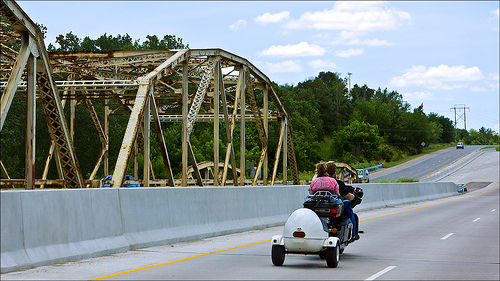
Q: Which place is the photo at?
A: It is at the road.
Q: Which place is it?
A: It is a road.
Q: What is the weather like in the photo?
A: It is cloudy.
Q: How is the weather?
A: It is cloudy.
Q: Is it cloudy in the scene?
A: Yes, it is cloudy.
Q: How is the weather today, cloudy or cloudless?
A: It is cloudy.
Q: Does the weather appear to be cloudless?
A: No, it is cloudy.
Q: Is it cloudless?
A: No, it is cloudy.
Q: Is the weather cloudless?
A: No, it is cloudy.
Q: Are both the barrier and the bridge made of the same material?
A: No, the barrier is made of cement and the bridge is made of metal.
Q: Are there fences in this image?
A: No, there are no fences.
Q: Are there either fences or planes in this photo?
A: No, there are no fences or planes.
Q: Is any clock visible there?
A: No, there are no clocks.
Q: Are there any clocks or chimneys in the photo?
A: No, there are no clocks or chimneys.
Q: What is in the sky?
A: The clouds are in the sky.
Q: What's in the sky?
A: The clouds are in the sky.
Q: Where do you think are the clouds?
A: The clouds are in the sky.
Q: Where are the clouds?
A: The clouds are in the sky.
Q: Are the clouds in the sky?
A: Yes, the clouds are in the sky.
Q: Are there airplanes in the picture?
A: No, there are no airplanes.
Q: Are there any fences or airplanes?
A: No, there are no airplanes or fences.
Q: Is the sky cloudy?
A: Yes, the sky is cloudy.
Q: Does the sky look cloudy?
A: Yes, the sky is cloudy.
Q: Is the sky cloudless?
A: No, the sky is cloudy.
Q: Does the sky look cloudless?
A: No, the sky is cloudy.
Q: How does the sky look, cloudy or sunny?
A: The sky is cloudy.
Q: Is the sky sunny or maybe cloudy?
A: The sky is cloudy.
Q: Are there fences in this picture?
A: No, there are no fences.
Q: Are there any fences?
A: No, there are no fences.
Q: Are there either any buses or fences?
A: No, there are no fences or buses.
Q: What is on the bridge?
A: The car is on the bridge.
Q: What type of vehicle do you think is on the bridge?
A: The vehicle is a car.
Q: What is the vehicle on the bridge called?
A: The vehicle is a car.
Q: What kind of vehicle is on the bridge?
A: The vehicle is a car.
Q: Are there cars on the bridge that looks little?
A: Yes, there is a car on the bridge.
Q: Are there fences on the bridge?
A: No, there is a car on the bridge.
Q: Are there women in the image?
A: Yes, there is a woman.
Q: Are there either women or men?
A: Yes, there is a woman.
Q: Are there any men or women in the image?
A: Yes, there is a woman.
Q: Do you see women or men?
A: Yes, there is a woman.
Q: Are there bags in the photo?
A: No, there are no bags.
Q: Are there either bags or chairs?
A: No, there are no bags or chairs.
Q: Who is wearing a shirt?
A: The woman is wearing a shirt.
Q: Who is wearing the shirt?
A: The woman is wearing a shirt.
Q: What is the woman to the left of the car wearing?
A: The woman is wearing a shirt.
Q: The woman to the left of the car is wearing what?
A: The woman is wearing a shirt.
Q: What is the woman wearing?
A: The woman is wearing a shirt.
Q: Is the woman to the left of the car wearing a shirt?
A: Yes, the woman is wearing a shirt.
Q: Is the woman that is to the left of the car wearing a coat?
A: No, the woman is wearing a shirt.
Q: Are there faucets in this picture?
A: No, there are no faucets.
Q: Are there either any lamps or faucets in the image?
A: No, there are no faucets or lamps.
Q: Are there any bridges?
A: Yes, there is a bridge.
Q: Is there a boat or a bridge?
A: Yes, there is a bridge.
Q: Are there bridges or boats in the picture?
A: Yes, there is a bridge.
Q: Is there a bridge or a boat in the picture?
A: Yes, there is a bridge.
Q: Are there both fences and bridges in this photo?
A: No, there is a bridge but no fences.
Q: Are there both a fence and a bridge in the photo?
A: No, there is a bridge but no fences.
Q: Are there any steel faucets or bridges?
A: Yes, there is a steel bridge.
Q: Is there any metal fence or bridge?
A: Yes, there is a metal bridge.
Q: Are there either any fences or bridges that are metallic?
A: Yes, the bridge is metallic.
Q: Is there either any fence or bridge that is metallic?
A: Yes, the bridge is metallic.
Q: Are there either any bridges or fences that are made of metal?
A: Yes, the bridge is made of metal.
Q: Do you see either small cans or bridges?
A: Yes, there is a small bridge.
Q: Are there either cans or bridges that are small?
A: Yes, the bridge is small.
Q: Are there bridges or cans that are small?
A: Yes, the bridge is small.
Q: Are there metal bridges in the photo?
A: Yes, there is a metal bridge.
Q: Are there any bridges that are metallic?
A: Yes, there is a bridge that is metallic.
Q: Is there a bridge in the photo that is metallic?
A: Yes, there is a bridge that is metallic.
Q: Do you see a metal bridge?
A: Yes, there is a bridge that is made of metal.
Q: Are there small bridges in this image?
A: Yes, there is a small bridge.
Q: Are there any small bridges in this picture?
A: Yes, there is a small bridge.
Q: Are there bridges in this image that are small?
A: Yes, there is a small bridge.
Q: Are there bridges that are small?
A: Yes, there is a bridge that is small.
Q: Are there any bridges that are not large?
A: Yes, there is a small bridge.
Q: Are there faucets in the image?
A: No, there are no faucets.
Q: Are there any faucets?
A: No, there are no faucets.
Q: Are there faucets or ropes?
A: No, there are no faucets or ropes.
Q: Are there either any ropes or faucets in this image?
A: No, there are no faucets or ropes.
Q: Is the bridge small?
A: Yes, the bridge is small.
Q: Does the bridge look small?
A: Yes, the bridge is small.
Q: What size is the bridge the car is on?
A: The bridge is small.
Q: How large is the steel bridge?
A: The bridge is small.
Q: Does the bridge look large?
A: No, the bridge is small.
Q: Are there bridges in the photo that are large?
A: No, there is a bridge but it is small.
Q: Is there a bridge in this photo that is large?
A: No, there is a bridge but it is small.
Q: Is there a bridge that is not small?
A: No, there is a bridge but it is small.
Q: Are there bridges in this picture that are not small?
A: No, there is a bridge but it is small.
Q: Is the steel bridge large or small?
A: The bridge is small.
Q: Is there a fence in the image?
A: No, there are no fences.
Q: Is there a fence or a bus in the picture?
A: No, there are no fences or buses.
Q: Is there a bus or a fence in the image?
A: No, there are no fences or buses.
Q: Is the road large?
A: Yes, the road is large.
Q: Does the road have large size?
A: Yes, the road is large.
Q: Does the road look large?
A: Yes, the road is large.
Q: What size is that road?
A: The road is large.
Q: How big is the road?
A: The road is large.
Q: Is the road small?
A: No, the road is large.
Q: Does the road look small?
A: No, the road is large.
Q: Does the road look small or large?
A: The road is large.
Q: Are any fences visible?
A: No, there are no fences.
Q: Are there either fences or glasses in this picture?
A: No, there are no fences or glasses.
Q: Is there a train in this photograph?
A: No, there are no trains.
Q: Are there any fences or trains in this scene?
A: No, there are no trains or fences.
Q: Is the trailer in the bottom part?
A: Yes, the trailer is in the bottom of the image.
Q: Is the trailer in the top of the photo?
A: No, the trailer is in the bottom of the image.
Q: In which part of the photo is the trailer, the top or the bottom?
A: The trailer is in the bottom of the image.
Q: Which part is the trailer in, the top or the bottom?
A: The trailer is in the bottom of the image.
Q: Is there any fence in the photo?
A: No, there are no fences.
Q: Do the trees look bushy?
A: Yes, the trees are bushy.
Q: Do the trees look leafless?
A: No, the trees are bushy.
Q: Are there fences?
A: No, there are no fences.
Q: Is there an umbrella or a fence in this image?
A: No, there are no fences or umbrellas.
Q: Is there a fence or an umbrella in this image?
A: No, there are no fences or umbrellas.